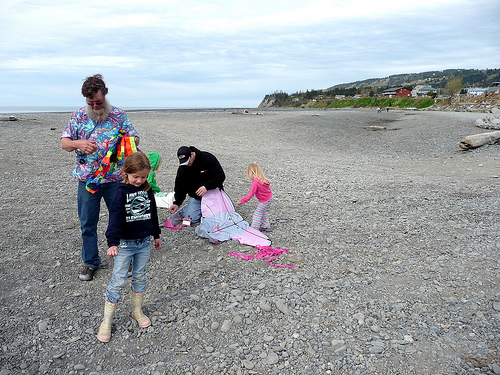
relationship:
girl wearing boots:
[97, 149, 166, 345] [96, 291, 155, 344]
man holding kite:
[60, 75, 142, 278] [81, 134, 137, 192]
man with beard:
[60, 75, 142, 278] [84, 100, 113, 125]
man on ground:
[170, 142, 232, 223] [6, 99, 500, 363]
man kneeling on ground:
[170, 142, 232, 223] [6, 99, 500, 363]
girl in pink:
[238, 161, 278, 230] [237, 175, 277, 208]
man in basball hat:
[170, 142, 232, 223] [175, 145, 194, 165]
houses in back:
[332, 72, 500, 98] [251, 0, 499, 111]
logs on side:
[459, 114, 499, 159] [409, 112, 500, 372]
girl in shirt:
[238, 161, 278, 230] [236, 177, 271, 213]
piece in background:
[457, 113, 500, 153] [7, 0, 495, 186]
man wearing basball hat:
[168, 142, 229, 223] [175, 145, 194, 165]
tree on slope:
[444, 75, 465, 94] [259, 77, 500, 107]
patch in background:
[321, 90, 431, 113] [7, 0, 495, 186]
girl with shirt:
[97, 149, 166, 345] [103, 182, 160, 244]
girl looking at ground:
[97, 149, 166, 345] [6, 99, 500, 363]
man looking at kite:
[60, 75, 142, 278] [81, 134, 137, 192]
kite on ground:
[194, 188, 278, 249] [6, 99, 500, 363]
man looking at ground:
[170, 142, 232, 223] [6, 99, 500, 363]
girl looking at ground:
[238, 161, 278, 230] [6, 99, 500, 363]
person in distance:
[385, 103, 391, 113] [5, 0, 499, 173]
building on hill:
[384, 84, 411, 97] [315, 82, 499, 112]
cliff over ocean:
[256, 61, 499, 111] [4, 105, 261, 116]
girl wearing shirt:
[97, 149, 166, 345] [108, 182, 160, 244]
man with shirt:
[170, 142, 232, 223] [170, 148, 226, 205]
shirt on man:
[170, 148, 226, 205] [170, 142, 232, 223]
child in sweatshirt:
[142, 148, 168, 192] [147, 152, 162, 192]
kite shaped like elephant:
[194, 188, 278, 249] [201, 190, 275, 248]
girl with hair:
[238, 161, 278, 230] [249, 158, 270, 188]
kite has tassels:
[194, 188, 278, 249] [231, 244, 296, 279]